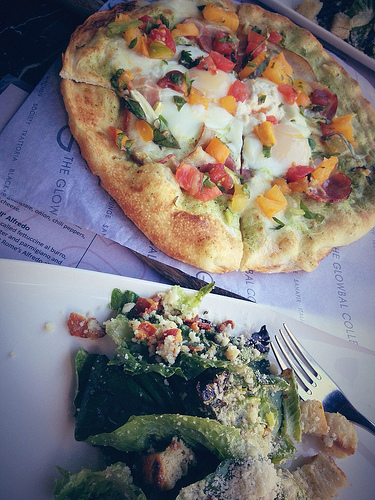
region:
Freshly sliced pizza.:
[36, 3, 370, 276]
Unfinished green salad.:
[11, 285, 362, 495]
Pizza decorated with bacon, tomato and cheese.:
[163, 17, 339, 124]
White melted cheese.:
[165, 105, 225, 129]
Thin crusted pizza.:
[60, 65, 117, 219]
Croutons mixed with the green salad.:
[301, 410, 347, 493]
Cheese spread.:
[219, 405, 281, 495]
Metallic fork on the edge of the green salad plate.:
[270, 320, 364, 415]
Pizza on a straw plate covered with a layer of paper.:
[57, 0, 372, 295]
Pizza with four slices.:
[60, 5, 370, 271]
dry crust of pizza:
[81, 102, 124, 165]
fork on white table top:
[274, 331, 324, 386]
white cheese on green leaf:
[119, 300, 188, 351]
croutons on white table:
[309, 385, 356, 494]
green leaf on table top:
[94, 370, 274, 463]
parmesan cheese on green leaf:
[227, 471, 299, 496]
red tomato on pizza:
[160, 130, 223, 209]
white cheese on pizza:
[240, 121, 315, 171]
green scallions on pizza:
[295, 204, 334, 238]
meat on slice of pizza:
[136, 78, 193, 139]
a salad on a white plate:
[52, 280, 300, 498]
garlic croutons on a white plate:
[300, 402, 358, 496]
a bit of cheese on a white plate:
[46, 322, 55, 334]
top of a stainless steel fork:
[269, 321, 374, 435]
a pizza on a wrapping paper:
[62, 2, 373, 273]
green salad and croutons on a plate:
[293, 1, 374, 64]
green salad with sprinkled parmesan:
[53, 279, 311, 498]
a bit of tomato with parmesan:
[67, 314, 105, 338]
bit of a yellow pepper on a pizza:
[201, 5, 236, 30]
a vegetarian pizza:
[61, 5, 373, 271]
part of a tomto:
[171, 155, 193, 192]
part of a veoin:
[179, 413, 214, 453]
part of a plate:
[24, 396, 71, 437]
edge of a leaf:
[183, 408, 223, 455]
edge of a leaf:
[352, 404, 367, 419]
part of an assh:
[222, 444, 261, 485]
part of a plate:
[11, 428, 36, 451]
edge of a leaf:
[181, 410, 214, 435]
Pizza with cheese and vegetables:
[58, 1, 374, 273]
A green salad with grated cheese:
[51, 279, 359, 499]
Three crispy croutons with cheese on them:
[297, 396, 358, 498]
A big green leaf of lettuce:
[71, 346, 302, 467]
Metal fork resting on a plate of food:
[268, 321, 374, 437]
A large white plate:
[0, 257, 374, 499]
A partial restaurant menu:
[0, 82, 171, 287]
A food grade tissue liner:
[0, 57, 374, 352]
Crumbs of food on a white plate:
[6, 307, 65, 358]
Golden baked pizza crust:
[57, 2, 374, 275]